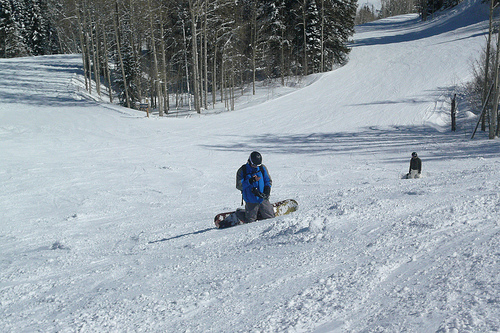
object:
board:
[214, 198, 300, 228]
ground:
[0, 102, 499, 333]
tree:
[72, 0, 99, 96]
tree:
[465, 0, 500, 139]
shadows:
[0, 54, 100, 109]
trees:
[60, 0, 364, 116]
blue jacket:
[235, 161, 273, 205]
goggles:
[249, 162, 261, 166]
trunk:
[84, 30, 106, 96]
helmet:
[247, 151, 262, 167]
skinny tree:
[200, 0, 209, 109]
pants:
[244, 199, 275, 222]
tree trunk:
[151, 45, 167, 117]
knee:
[245, 218, 256, 224]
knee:
[263, 214, 277, 220]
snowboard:
[400, 173, 415, 180]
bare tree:
[140, 0, 175, 119]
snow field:
[1, 0, 495, 333]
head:
[247, 150, 262, 168]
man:
[234, 150, 276, 223]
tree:
[298, 0, 358, 79]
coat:
[409, 158, 423, 176]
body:
[236, 163, 276, 223]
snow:
[0, 0, 500, 333]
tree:
[237, 0, 277, 96]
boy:
[406, 152, 422, 179]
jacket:
[409, 157, 422, 174]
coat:
[236, 163, 273, 204]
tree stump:
[449, 93, 460, 133]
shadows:
[192, 125, 500, 162]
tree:
[0, 0, 69, 57]